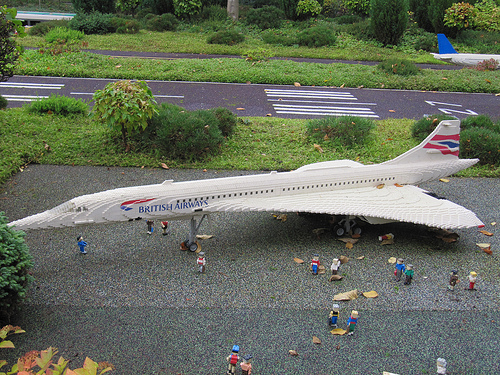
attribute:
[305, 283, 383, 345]
lego — people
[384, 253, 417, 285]
spectators — looking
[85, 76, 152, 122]
leaves — green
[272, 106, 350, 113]
lines — straight white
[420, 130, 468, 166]
tail — red, blue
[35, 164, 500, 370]
tarmac — light grey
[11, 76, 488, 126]
runway — make believe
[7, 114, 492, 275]
plane — british airways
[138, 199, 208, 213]
logo — blue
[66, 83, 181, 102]
line — long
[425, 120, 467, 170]
logo — British Airways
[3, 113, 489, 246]
plane — made of legos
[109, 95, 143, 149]
tree — model 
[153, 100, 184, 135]
brush — model 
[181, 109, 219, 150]
brush — model 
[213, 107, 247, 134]
brush — model 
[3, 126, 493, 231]
airplane — model , legos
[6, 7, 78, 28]
building — small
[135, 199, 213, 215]
british airways — in blue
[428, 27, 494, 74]
tail — legos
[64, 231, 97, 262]
figurine — blue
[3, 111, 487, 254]
airplane — Concorde, lego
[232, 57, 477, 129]
lines — white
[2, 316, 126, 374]
leaves — yellow and red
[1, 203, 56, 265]
nose — white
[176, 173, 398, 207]
small windows — long row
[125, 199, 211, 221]
logo — red, blue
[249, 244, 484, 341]
figures — small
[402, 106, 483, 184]
tail — Concorde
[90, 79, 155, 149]
bush — green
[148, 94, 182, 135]
bush — green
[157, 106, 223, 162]
bush — green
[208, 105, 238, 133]
bush — green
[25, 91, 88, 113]
bush — green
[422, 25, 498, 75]
plane — model , legos